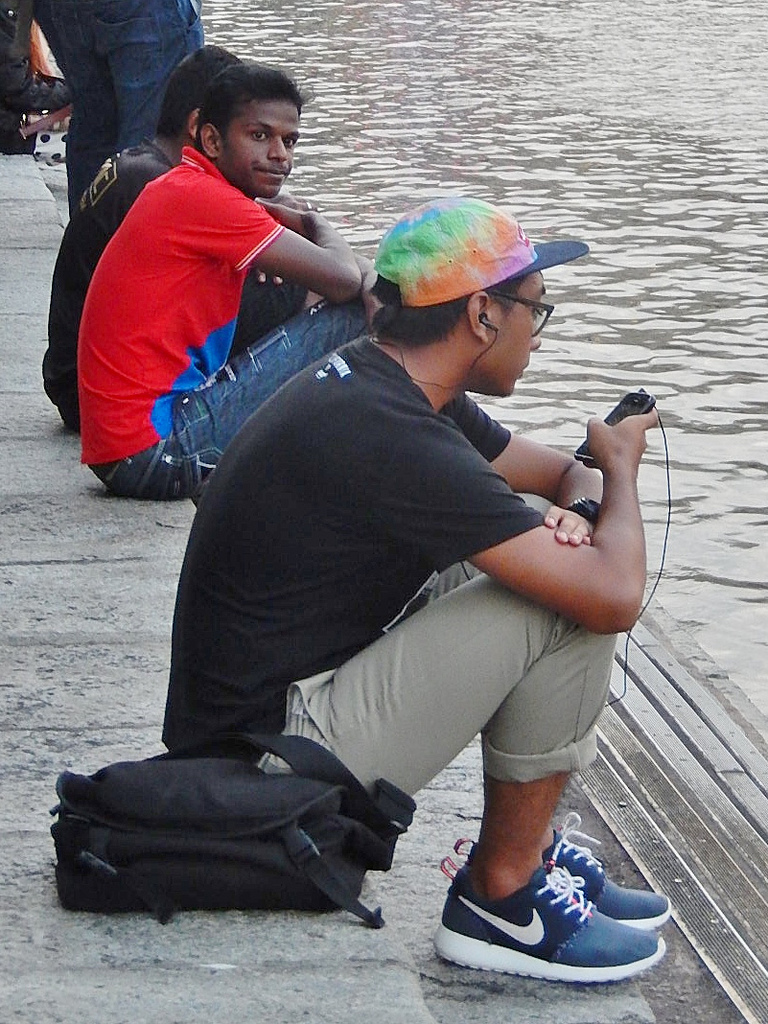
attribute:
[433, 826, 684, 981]
sneakers — blue, nike, a pair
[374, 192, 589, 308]
cap — colorful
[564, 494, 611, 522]
watch — black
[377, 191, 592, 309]
hat — colorful, pastel hat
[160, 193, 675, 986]
person — sitting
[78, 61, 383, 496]
person — sitting down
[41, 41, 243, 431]
person — standing up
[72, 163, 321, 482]
shirt — red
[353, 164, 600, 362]
cap — ball cap